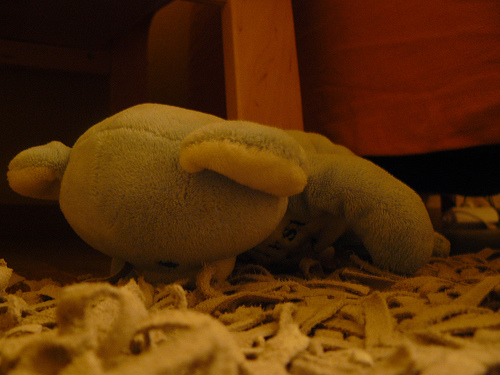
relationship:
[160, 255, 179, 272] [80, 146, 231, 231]
eye of bear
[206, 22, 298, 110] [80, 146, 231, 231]
chair leg behind bear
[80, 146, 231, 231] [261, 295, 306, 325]
bear on floor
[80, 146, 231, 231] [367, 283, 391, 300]
bear on flooring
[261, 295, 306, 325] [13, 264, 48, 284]
floor has threads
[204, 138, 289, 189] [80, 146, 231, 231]
ear on bear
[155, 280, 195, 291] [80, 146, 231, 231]
nose on bear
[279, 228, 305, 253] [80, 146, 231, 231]
writing on bear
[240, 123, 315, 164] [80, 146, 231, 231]
fur on bear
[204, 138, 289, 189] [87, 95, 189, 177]
ear attached to head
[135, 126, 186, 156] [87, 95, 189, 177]
seam on head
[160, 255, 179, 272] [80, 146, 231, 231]
eye on bear